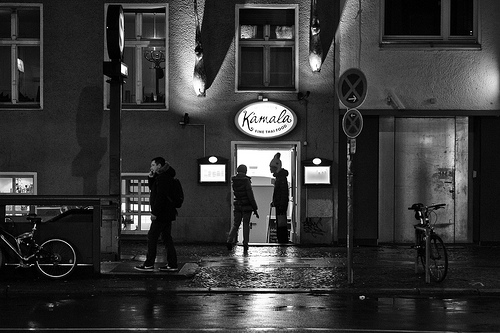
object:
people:
[131, 153, 290, 273]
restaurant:
[62, 67, 481, 280]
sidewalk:
[159, 246, 447, 294]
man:
[132, 157, 185, 274]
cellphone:
[150, 169, 154, 175]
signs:
[337, 67, 368, 138]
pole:
[344, 155, 355, 288]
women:
[227, 164, 260, 248]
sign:
[235, 100, 299, 139]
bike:
[407, 203, 449, 283]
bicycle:
[0, 217, 77, 279]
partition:
[39, 198, 121, 246]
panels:
[198, 155, 229, 186]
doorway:
[230, 140, 298, 244]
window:
[237, 8, 298, 92]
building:
[38, 37, 482, 233]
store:
[47, 31, 465, 188]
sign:
[337, 68, 368, 109]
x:
[344, 76, 362, 100]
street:
[50, 282, 489, 330]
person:
[266, 150, 303, 244]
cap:
[270, 152, 282, 172]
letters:
[241, 109, 292, 133]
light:
[179, 63, 210, 109]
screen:
[304, 166, 331, 184]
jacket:
[148, 175, 180, 221]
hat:
[269, 153, 282, 173]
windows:
[0, 0, 482, 110]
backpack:
[168, 172, 185, 208]